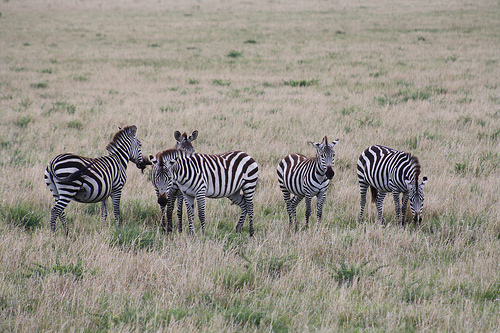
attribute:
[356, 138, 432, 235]
zebra —  five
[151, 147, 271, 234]
zebra — in center 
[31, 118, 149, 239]
zebra — group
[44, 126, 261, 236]
three zebras —  Three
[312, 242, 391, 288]
dead grass —  almost dead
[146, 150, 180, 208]
head — down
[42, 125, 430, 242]
zebra — center 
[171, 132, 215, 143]
ears —  rounded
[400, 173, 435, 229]
zebra — grazing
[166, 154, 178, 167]
stripes —  black and white 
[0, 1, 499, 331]
grass — tan , green , brown,  almost dead 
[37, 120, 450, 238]
zebra —  Two,  nervous,  in herd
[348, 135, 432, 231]
zebras —  Two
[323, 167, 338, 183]
snout —    black,  animal's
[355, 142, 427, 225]
zebra — cute ,  little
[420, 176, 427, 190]
ear —   black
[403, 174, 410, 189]
ear —   black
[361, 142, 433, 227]
zebra — five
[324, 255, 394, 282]
weed patch — green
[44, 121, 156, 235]
zebra — standing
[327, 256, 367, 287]
bush — green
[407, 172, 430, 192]
neck — bent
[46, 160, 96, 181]
tail —   zebra's,    black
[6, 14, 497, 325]
field — is open, large , grassy 